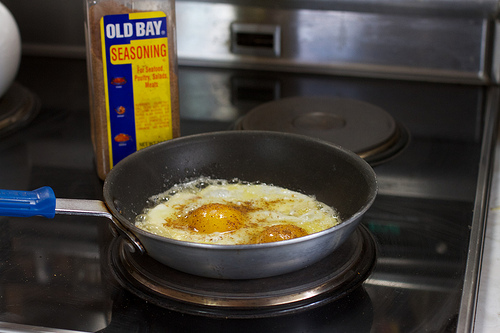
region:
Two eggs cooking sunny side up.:
[133, 179, 337, 248]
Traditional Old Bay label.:
[98, 9, 178, 170]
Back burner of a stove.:
[234, 92, 399, 165]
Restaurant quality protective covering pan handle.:
[0, 181, 57, 223]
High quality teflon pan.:
[0, 126, 381, 282]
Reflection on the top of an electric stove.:
[367, 216, 404, 239]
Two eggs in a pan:
[111, 130, 374, 281]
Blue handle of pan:
[0, 190, 66, 215]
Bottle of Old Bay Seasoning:
[82, 0, 178, 184]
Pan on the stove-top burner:
[99, 125, 392, 317]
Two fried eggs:
[139, 180, 335, 243]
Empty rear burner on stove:
[239, 88, 405, 154]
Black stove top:
[0, 53, 499, 325]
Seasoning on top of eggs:
[169, 196, 293, 238]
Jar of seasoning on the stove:
[84, 0, 177, 181]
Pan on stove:
[0, 128, 379, 277]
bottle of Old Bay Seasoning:
[87, 0, 174, 177]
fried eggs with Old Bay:
[137, 182, 338, 245]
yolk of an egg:
[185, 203, 245, 232]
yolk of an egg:
[251, 225, 304, 245]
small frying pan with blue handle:
[0, 132, 379, 277]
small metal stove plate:
[241, 95, 396, 156]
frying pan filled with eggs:
[0, 129, 380, 279]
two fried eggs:
[140, 180, 340, 245]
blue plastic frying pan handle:
[0, 186, 57, 221]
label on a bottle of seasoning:
[102, 10, 174, 173]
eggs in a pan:
[44, 85, 369, 297]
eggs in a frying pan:
[54, 95, 293, 285]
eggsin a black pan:
[36, 105, 353, 330]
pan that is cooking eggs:
[94, 80, 476, 323]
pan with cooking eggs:
[136, 98, 417, 324]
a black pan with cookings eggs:
[85, 72, 471, 325]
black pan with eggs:
[109, 95, 475, 300]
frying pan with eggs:
[92, 101, 442, 329]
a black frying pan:
[99, 111, 394, 318]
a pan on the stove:
[83, 78, 417, 331]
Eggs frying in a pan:
[104, 139, 338, 251]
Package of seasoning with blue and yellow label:
[93, 7, 172, 149]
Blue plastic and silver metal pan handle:
[1, 187, 107, 222]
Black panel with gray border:
[223, 19, 290, 69]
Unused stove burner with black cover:
[256, 87, 409, 164]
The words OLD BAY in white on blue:
[104, 18, 165, 42]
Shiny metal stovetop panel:
[212, 4, 457, 71]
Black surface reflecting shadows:
[188, 72, 252, 115]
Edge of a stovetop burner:
[166, 274, 322, 323]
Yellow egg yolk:
[175, 203, 256, 232]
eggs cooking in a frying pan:
[127, 164, 327, 257]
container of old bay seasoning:
[86, 6, 186, 173]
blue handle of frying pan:
[2, 179, 52, 218]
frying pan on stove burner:
[64, 129, 392, 319]